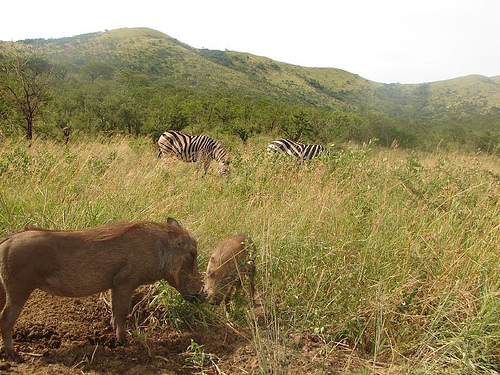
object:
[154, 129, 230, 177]
zebras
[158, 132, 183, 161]
stripes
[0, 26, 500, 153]
hill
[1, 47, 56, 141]
trees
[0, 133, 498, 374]
grass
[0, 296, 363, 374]
dirt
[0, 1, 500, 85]
sky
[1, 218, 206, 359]
animals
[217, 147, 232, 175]
head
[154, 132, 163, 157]
tail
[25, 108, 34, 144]
trunk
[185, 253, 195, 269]
eye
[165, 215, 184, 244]
ear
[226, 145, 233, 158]
ears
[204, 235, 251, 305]
pig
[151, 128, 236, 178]
zebra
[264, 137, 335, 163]
zebra